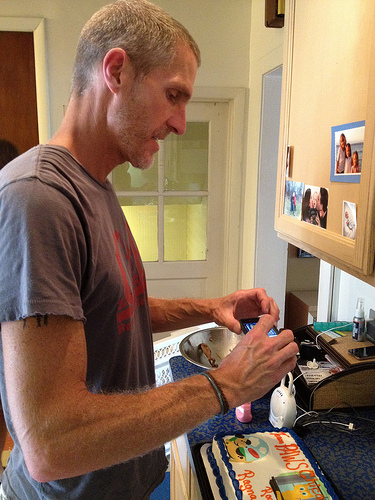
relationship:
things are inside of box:
[294, 307, 373, 399] [278, 312, 370, 415]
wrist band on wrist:
[199, 366, 228, 416] [172, 366, 234, 411]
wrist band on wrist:
[198, 371, 225, 419] [202, 364, 240, 413]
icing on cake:
[234, 437, 326, 477] [208, 426, 308, 498]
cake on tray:
[203, 424, 338, 498] [188, 434, 338, 498]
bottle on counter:
[348, 297, 364, 342] [169, 321, 374, 498]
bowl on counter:
[179, 325, 243, 367] [169, 321, 374, 498]